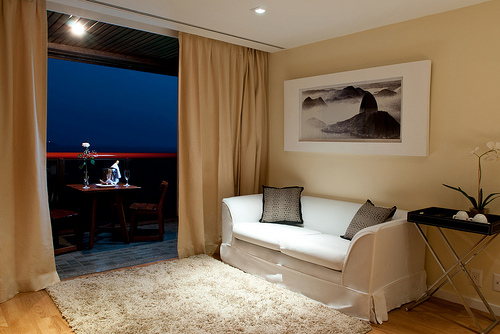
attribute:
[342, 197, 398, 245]
pillow — grey, black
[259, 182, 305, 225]
pillow — black, grey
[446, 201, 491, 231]
cups — white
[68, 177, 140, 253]
table — dining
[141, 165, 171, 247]
chairs — dining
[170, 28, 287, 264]
curtains — beige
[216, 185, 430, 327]
couch — rounded, white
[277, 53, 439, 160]
frame — white, black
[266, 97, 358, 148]
wall — metal, barrier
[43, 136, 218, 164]
bar — red, metal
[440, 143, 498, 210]
flower — white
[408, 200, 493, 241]
tray — black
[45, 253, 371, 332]
rug — beige, shag, area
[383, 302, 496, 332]
flooring — light, wooden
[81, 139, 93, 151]
rose — pink, single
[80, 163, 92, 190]
vase — crystal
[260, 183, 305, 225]
throw pillow — black, grey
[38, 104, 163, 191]
sign — green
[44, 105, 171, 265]
pole — black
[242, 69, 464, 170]
art — white, framed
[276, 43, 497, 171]
sign — green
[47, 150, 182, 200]
balcony — red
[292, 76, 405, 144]
art — white